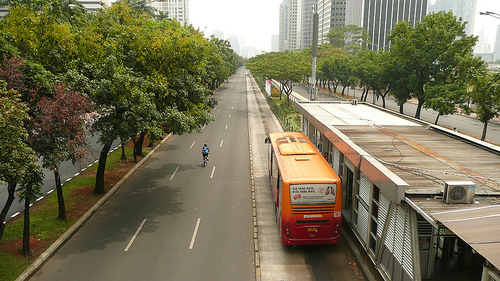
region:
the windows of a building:
[367, 3, 384, 28]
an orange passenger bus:
[259, 122, 347, 257]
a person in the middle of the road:
[197, 143, 216, 171]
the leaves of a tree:
[134, 43, 174, 102]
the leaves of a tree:
[397, 31, 427, 76]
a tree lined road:
[203, 38, 294, 80]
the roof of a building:
[350, 118, 464, 162]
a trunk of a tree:
[91, 145, 111, 200]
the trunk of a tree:
[50, 174, 70, 224]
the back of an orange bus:
[285, 178, 344, 249]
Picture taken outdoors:
[9, 13, 497, 273]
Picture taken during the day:
[13, 14, 480, 263]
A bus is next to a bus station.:
[249, 128, 357, 255]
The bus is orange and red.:
[275, 152, 345, 234]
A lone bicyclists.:
[193, 143, 212, 158]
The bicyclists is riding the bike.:
[191, 135, 214, 165]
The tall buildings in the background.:
[286, 10, 390, 30]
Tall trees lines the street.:
[66, 23, 188, 119]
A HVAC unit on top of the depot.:
[444, 182, 475, 200]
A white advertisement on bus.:
[293, 183, 333, 202]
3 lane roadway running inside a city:
[18, 60, 260, 280]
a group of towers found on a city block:
[271, 0, 498, 63]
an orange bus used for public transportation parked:
[264, 128, 343, 252]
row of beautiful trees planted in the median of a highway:
[0, 0, 243, 280]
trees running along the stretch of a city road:
[4, 0, 244, 280]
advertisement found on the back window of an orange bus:
[286, 181, 338, 205]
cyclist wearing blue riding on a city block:
[201, 141, 210, 166]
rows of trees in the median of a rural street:
[246, 0, 499, 143]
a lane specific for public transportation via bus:
[246, 58, 368, 278]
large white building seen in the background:
[141, 0, 190, 29]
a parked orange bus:
[266, 130, 345, 248]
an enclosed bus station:
[291, 95, 498, 277]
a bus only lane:
[244, 61, 371, 279]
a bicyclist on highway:
[199, 142, 210, 167]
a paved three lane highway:
[29, 66, 248, 278]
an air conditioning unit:
[444, 179, 476, 206]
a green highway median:
[249, 60, 306, 132]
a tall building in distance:
[279, 0, 299, 52]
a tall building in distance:
[299, 1, 315, 47]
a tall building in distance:
[313, 0, 347, 46]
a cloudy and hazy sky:
[191, 1, 281, 56]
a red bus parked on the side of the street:
[260, 128, 346, 251]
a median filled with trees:
[0, 0, 175, 280]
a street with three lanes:
[31, 65, 261, 279]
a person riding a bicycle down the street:
[200, 140, 212, 167]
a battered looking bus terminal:
[292, 95, 499, 280]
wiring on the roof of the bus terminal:
[349, 120, 499, 201]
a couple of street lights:
[476, 7, 499, 21]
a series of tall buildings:
[268, 0, 478, 65]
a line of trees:
[245, 9, 499, 140]